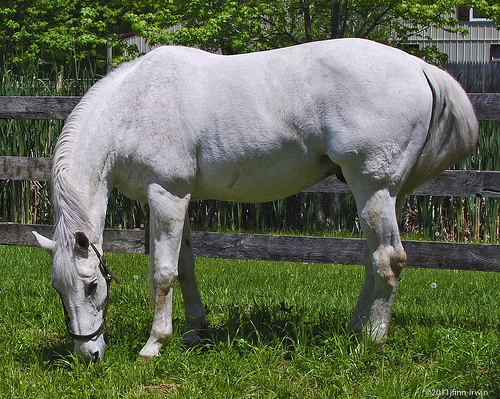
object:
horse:
[31, 36, 479, 365]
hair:
[50, 168, 99, 250]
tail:
[395, 61, 479, 210]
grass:
[20, 329, 171, 389]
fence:
[0, 93, 499, 272]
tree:
[2, 0, 107, 158]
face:
[50, 240, 109, 363]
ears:
[31, 230, 58, 255]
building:
[377, 4, 499, 93]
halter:
[62, 242, 122, 340]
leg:
[327, 121, 431, 355]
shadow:
[182, 305, 347, 348]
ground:
[0, 230, 499, 397]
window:
[469, 6, 496, 23]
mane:
[49, 52, 143, 182]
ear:
[72, 230, 93, 275]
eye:
[83, 277, 97, 299]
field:
[0, 201, 499, 397]